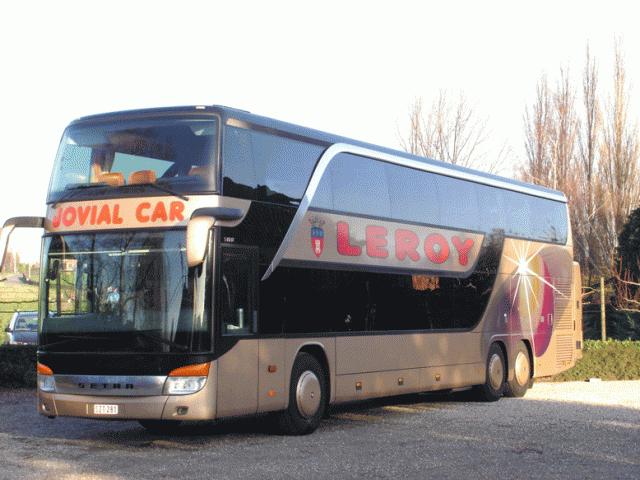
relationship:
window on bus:
[237, 112, 266, 186] [12, 106, 593, 464]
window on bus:
[268, 126, 302, 196] [12, 106, 593, 464]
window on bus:
[335, 151, 357, 206] [12, 106, 593, 464]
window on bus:
[383, 150, 411, 221] [12, 106, 593, 464]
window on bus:
[450, 163, 468, 244] [17, 101, 604, 431]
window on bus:
[480, 182, 503, 225] [17, 101, 604, 431]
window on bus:
[512, 195, 533, 229] [17, 101, 604, 431]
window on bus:
[245, 261, 298, 324] [17, 101, 604, 431]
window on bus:
[25, 247, 278, 375] [26, 83, 589, 444]